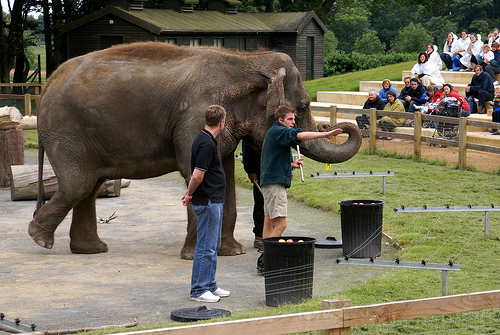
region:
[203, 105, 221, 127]
Man has black hair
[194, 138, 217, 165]
Man wears black shirt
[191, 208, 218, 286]
Man wears blue jeans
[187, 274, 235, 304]
White sneakers on man's feet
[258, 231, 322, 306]
Black garbage can on ground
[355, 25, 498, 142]
Crowd sitting on benches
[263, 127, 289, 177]
Man wears green sweater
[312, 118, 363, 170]
Elephants trunk is curled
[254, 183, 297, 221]
Man wears beige shorts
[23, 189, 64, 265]
Elephants leg is raised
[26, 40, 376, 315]
two men beside an elephant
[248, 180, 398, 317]
two black barrels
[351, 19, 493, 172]
people are watching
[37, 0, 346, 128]
a brown cabin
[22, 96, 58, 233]
the tail is long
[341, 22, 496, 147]
people are sitting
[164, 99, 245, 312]
the man is wearing blue jeans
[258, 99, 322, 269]
the man is wearing khaki shorts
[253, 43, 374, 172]
the elephant's trunk is curled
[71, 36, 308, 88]
the elephant has hair on it's back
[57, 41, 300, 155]
an elephant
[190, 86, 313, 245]
two men handling an elephant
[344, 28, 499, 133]
an audience watching an elephant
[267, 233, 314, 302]
a black bucket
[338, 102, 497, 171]
a wooden fency separating the elephant and audience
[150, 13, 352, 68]
a brown small house behind the audience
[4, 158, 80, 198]
a wooden tree stump on the ground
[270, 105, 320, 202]
a man holding a pole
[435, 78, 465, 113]
a woman in a red jacket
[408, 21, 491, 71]
a bunch of people wearing white poncho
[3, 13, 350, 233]
the elephant is brown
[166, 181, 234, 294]
man's pants are blue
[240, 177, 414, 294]
the baskets are black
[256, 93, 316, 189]
man's shirt is green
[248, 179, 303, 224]
man's pants are khaki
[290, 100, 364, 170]
elephant's trunk is curled up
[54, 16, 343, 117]
elephant is hairy on top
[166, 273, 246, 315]
man's shoes are white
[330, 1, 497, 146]
people are watching elephant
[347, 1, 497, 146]
people are sitting down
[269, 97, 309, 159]
Man has brown hair.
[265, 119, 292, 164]
Man is wearing blue shirt.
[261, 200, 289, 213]
Man is wearing khaki shorts.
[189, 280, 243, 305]
Man is wearing white shoes.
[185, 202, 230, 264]
Man is wearing blue jeans.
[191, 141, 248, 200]
Man is wearing black polo shirt.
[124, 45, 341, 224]
2 men standing near elephant.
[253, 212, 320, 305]
Large black garbage can.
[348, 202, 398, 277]
Large black garbage can.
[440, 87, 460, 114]
Person wearing red shirt.